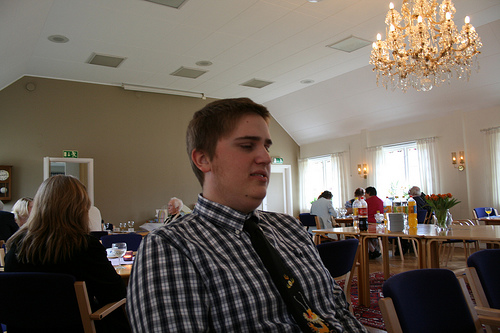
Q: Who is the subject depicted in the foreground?
A: Adult male.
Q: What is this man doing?
A: Sitting.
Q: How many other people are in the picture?
A: Seven.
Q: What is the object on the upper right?
A: Chandelier.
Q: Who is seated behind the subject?
A: Adult female.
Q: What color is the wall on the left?
A: Beige.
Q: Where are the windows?
A: On the wall on the right.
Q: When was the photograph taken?
A: Noon.